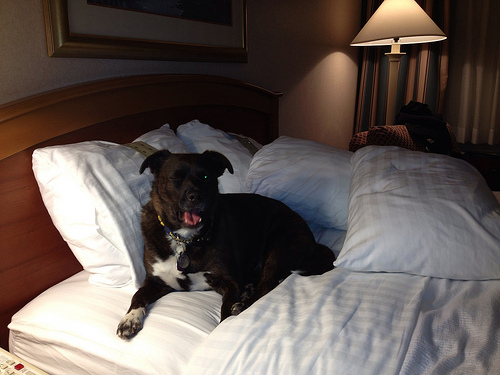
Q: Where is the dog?
A: On bed.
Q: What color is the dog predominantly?
A: Brown.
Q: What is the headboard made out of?
A: Wood.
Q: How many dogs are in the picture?
A: One.